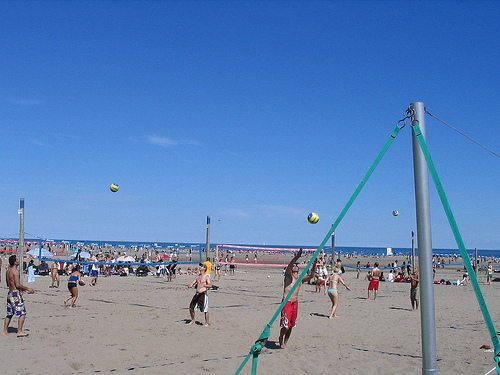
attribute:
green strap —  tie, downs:
[209, 110, 424, 374]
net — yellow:
[211, 236, 336, 273]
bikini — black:
[64, 277, 81, 291]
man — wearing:
[4, 255, 27, 335]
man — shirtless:
[181, 263, 213, 328]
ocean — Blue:
[0, 237, 499, 257]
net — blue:
[24, 230, 210, 267]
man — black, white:
[183, 252, 221, 332]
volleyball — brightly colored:
[308, 212, 319, 224]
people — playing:
[367, 262, 381, 298]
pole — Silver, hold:
[400, 98, 441, 374]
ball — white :
[306, 210, 323, 225]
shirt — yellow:
[202, 257, 214, 276]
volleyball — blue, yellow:
[304, 210, 323, 227]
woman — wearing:
[316, 264, 355, 322]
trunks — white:
[4, 254, 36, 337]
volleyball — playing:
[306, 210, 321, 225]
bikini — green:
[322, 275, 342, 298]